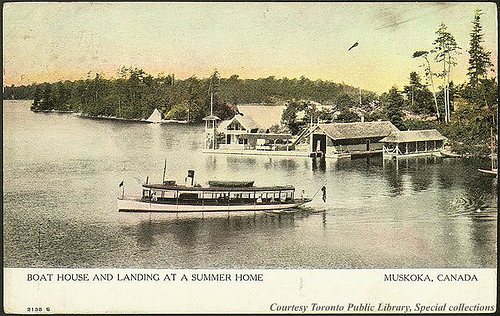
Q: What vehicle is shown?
A: A boat.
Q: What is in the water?
A: A boat.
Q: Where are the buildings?
A: On the shore.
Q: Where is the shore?
A: Behind the water.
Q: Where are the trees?
A: On the land.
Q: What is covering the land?
A: Trees.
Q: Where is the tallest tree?
A: On the right.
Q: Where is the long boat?
A: On the water.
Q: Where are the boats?
A: On the water.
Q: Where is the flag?
A: On the back of the boat.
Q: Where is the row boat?
A: On top of the boat.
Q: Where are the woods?
A: Along the river.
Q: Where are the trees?
A: By the river.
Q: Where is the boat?
A: On the water.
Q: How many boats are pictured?
A: One.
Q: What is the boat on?
A: A lake.